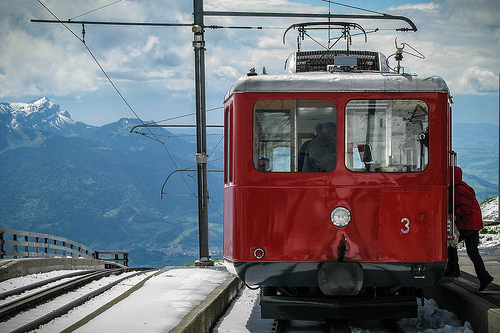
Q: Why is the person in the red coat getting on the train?
A: To catch a ride.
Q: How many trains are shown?
A: One.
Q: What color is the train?
A: Red.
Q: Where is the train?
A: On the tracks.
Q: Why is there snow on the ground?
A: It's winter.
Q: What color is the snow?
A: White.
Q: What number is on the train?
A: 3.